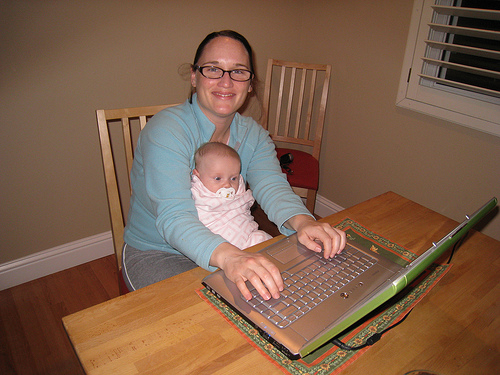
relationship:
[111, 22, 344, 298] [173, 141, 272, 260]
woman holding baby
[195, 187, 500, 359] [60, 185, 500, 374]
laptop on table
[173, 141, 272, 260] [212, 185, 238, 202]
baby has pacifier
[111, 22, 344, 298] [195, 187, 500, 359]
woman on laptop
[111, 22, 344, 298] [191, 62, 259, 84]
woman wearing glasses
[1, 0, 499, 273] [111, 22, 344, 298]
wall behind woman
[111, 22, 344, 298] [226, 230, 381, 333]
woman typing on keyboard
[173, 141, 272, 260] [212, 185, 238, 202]
baby using pacifier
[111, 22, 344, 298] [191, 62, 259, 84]
woman has glasses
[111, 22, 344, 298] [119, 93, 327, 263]
woman has shirt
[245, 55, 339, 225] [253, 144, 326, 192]
chair has seat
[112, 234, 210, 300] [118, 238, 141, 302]
pants have line